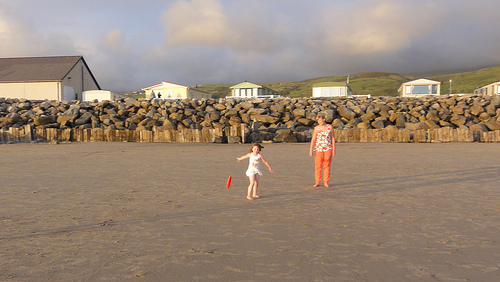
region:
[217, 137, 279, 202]
a girl is playing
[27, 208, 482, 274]
the beach sand is brown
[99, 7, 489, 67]
the sky is cloudy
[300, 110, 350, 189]
the woman is wearing orange and white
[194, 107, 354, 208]
the woman is watching the little girl play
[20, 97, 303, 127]
a stone seawall in the background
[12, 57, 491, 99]
multiple small buildings are a lined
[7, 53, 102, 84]
the roof top is brown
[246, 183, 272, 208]
the girl is barefoot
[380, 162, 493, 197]
their shadows are on the beach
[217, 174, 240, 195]
a red frisbee in the air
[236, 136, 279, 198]
a little girl wear a white dress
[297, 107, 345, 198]
a woman wearing orange pants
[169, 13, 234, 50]
wispy white cloud in th sky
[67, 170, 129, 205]
gray sand on the beach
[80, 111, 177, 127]
a pile of large rocks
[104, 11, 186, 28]
clear blue sky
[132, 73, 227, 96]
small white house behind the girl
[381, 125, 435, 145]
a small wooden fence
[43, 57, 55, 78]
black tiled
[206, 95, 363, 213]
A older woman and a small girl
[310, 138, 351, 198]
Older woman is wearing orange pants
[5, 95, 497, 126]
A pile of rocks are in the background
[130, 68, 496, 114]
Houses are in the background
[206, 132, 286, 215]
Small girl is throwing a Frisbee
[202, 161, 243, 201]
The Frisbee is bright red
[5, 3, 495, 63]
The sky is cloudy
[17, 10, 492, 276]
Photo was taken in the daytime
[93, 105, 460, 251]
Two people on a beach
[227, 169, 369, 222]
Two people are barefoot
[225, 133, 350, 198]
Girl in a white dress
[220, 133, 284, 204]
Girl on a beach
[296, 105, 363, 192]
Woman on a beach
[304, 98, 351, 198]
Woman in orange and white on a beach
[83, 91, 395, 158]
Rock wall by a beach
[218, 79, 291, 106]
House by a rock wall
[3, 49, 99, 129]
Building by a rock wall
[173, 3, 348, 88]
Clouds in a sky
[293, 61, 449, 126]
Green hill by houses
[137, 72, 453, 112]
Houses along a rock wall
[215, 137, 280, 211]
Little girl throwing a frisbee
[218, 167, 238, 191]
Frisbee is red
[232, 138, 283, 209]
Little girl wears white dress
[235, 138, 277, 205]
Girl has arms extended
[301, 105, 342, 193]
Woman wears orange pants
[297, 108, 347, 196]
Woman wears a tank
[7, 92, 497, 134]
Fence of stones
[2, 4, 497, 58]
Sky is blue with white clouds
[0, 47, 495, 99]
Homes behind stone fence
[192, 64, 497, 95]
Hill behind homes